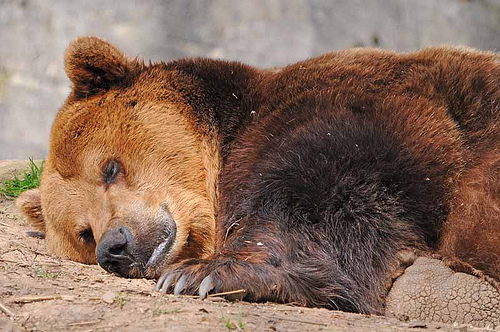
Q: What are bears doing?
A: Lying down.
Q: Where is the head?
A: On bear.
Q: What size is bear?
A: Large.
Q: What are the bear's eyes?
A: Closed.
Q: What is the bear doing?
A: Laying.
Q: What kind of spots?
A: Dark brown.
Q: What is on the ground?
A: Twigs and straws.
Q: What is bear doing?
A: Sleeping.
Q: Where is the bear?
A: On the ground.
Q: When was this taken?
A: During the day.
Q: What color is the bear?
A: Brown.